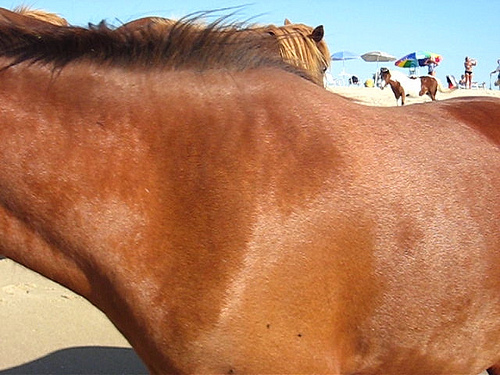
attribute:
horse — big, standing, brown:
[0, 4, 499, 373]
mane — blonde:
[144, 18, 329, 83]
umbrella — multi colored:
[396, 52, 443, 70]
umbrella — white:
[362, 51, 398, 89]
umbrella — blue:
[329, 51, 359, 82]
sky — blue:
[1, 1, 500, 87]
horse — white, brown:
[379, 72, 438, 106]